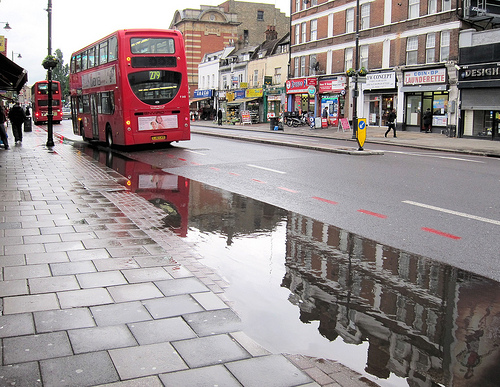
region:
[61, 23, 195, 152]
a double decker bus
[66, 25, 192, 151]
a red double decker bus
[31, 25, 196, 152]
two double deckers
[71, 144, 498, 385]
a water puddle on the side of the road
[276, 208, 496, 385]
reflection of building on puddle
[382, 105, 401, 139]
person walking in the sidewalk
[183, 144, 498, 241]
broken white and red lines on road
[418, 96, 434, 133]
a person by the door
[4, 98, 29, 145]
back of the person walking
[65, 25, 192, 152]
back and side of the bus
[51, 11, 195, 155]
bus in right lane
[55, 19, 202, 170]
bus in front is red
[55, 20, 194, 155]
bus is double decker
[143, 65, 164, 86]
279 number on front of bus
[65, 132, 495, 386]
large puddle on side of road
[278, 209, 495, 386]
building reflected in water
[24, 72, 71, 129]
red bus behind front bus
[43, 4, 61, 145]
tall lamp post on sidewalk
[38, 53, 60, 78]
plant hanging on post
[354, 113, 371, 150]
yellow flag on pole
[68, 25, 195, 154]
red double decker bus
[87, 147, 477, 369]
puddle of water along the road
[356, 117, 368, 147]
bright yellow sign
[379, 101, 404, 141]
person walking on the sidewalk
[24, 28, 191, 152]
pair of large red buses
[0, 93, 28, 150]
people on the sidewalk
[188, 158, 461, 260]
red painted lines on the road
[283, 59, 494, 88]
signs on the buildings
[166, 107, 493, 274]
road still damp from rain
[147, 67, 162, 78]
bus number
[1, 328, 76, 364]
sidewalk brick next to sidewalk brick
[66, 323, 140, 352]
sidewalk brick next to sidewalk brick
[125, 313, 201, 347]
sidewalk brick next to sidewalk brick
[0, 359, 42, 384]
sidewalk brick next to sidewalk brick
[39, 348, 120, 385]
sidewalk brick next to sidewalk brick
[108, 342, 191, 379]
sidewalk brick next to sidewalk brick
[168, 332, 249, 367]
sidewalk brick next to sidewalk brick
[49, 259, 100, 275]
sidewalk brick next to sidewalk brick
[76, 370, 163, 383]
sidewalk brick next to sidewalk brick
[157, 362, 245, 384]
sidewalk brick next to sidewalk brick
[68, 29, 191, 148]
The biggest red double decker bus.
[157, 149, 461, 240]
Red dashes going down the road.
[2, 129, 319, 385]
A large rectangle walkway that is wet.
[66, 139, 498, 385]
A long puddle of water going down the side of the road.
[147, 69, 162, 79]
279 on the back of a bus.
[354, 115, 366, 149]
A yellow road sign with a blue circle and white arrow in it.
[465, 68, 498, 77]
The word DESIGN on a building front.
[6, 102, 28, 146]
A man walking down the sidewalk with all black on.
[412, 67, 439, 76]
The blue words COIN OP.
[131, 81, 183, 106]
Curved window under the number 279 on a bus.